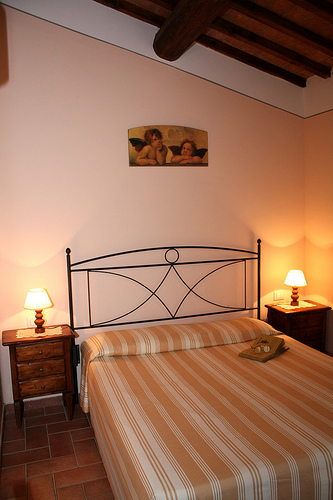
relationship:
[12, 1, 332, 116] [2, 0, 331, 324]
border around wall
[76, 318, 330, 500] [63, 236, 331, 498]
bedspread on bed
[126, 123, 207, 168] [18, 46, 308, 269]
picture on wall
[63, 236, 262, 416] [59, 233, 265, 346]
bed frame on frame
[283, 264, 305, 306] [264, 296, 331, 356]
lamp on table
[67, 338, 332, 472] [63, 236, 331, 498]
bedspread on bed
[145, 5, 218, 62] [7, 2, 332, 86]
beam in ceiling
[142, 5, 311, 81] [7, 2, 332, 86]
beam in ceiling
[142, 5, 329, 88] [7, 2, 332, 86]
beam in ceiling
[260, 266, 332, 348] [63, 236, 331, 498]
nightstand on right side of bed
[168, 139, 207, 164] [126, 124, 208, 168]
angel on picture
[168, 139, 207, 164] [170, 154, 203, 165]
angel resting on arms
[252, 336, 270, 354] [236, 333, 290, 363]
eyeglasses on top of book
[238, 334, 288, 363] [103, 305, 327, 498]
book on bed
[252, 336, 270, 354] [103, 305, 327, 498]
eyeglasses on bed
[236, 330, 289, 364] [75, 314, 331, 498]
towels on bed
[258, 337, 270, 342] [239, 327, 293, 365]
letters on towel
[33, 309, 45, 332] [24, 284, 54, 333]
base on lamp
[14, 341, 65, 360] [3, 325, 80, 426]
drawer on table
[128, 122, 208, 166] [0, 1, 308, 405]
painting on wall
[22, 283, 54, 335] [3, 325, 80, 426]
lamp on table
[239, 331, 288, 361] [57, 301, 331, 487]
book on top of bed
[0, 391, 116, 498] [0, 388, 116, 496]
tiles on floor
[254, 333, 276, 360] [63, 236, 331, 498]
eyeglasses on bed